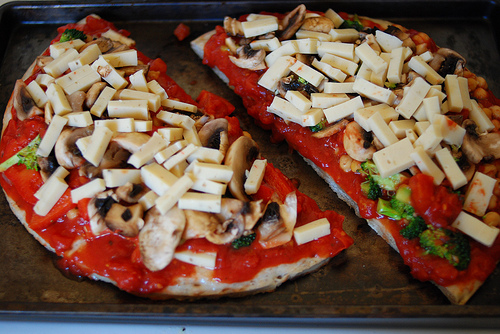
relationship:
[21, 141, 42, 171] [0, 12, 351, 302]
broccoli on pizza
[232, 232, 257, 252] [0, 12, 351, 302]
broccoli on pizza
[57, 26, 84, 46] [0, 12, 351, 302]
broccoli on pizza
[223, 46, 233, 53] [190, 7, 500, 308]
broccoli on pizza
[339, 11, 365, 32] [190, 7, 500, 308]
broccoli on pizza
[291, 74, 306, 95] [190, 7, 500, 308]
broccoli on pizza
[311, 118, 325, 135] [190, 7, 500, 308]
broccoli on pizza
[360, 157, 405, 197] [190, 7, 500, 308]
broccoli on pizza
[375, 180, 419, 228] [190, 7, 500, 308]
broccoli on pizza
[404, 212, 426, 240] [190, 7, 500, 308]
broccoli on pizza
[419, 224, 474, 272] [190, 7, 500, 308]
broccoli on pizza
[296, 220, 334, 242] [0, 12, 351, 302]
cheese on pizza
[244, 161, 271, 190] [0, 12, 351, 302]
cheese on pizza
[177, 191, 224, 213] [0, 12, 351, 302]
cheese on pizza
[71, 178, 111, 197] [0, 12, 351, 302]
cheese on pizza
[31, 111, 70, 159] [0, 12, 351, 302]
cheese on pizza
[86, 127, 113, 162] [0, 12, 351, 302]
cheese on pizza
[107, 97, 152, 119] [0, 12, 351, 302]
cheese on pizza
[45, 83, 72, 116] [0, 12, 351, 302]
cheese on pizza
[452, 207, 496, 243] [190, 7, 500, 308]
cheese on pizza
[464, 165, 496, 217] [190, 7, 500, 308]
cheese on pizza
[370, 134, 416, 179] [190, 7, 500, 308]
cheese on pizza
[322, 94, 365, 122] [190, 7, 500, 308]
cheese on pizza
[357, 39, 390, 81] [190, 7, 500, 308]
cheese on pizza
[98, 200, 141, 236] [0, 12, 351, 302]
mushroom on pizza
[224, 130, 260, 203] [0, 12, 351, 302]
mushroom on pizza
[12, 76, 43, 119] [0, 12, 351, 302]
mushroom on pizza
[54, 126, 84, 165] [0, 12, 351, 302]
mushroom on pizza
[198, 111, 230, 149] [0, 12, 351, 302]
mushroom on pizza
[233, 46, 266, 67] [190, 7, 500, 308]
mushroom on pizza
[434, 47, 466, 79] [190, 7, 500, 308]
mushroom on pizza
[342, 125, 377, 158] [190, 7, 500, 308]
mushroom on pizza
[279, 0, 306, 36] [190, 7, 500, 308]
mushroom on pizza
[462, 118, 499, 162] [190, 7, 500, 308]
mushroom on pizza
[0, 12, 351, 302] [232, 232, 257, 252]
pizza has broccoli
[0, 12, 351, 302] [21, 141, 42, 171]
pizza has broccoli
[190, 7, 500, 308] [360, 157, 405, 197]
pizza has broccoli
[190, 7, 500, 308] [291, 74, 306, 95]
pizza has broccoli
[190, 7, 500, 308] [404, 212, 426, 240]
pizza has broccoli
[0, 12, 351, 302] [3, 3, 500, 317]
pizza on pan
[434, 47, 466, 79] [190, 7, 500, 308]
mushroom on edge of pizza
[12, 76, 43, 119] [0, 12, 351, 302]
mushroom on edge of pizza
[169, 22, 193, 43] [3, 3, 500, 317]
tomato on pan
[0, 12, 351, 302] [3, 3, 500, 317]
pizza in pan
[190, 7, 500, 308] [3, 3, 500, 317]
pizza in pan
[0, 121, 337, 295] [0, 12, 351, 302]
sauce on pizza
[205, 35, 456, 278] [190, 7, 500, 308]
sauce on pizza